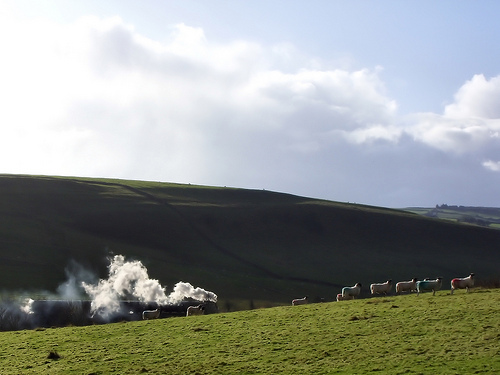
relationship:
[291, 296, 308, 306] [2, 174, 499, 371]
animal in field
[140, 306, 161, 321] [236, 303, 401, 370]
animal in field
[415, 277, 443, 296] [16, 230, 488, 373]
animal in field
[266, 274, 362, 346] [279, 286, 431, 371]
sheep in field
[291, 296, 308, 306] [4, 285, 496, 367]
animal in field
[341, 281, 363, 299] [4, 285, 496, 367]
animals in field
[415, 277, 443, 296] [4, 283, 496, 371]
animal standing on grass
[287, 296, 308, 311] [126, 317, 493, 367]
animal standing in field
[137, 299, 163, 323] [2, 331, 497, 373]
animal standing in field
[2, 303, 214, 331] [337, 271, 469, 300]
train behind animals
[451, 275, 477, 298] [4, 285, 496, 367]
sheep in field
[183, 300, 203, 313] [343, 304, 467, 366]
sheep on grass